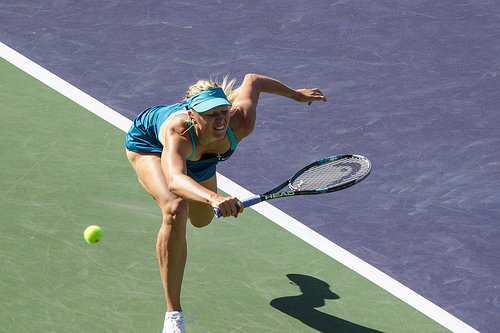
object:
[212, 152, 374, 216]
racket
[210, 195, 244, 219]
hand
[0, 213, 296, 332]
blue green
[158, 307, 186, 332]
sneaker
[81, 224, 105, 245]
ball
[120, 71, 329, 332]
woman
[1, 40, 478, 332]
line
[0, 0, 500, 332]
court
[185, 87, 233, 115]
visor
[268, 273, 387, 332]
shadow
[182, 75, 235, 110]
hair